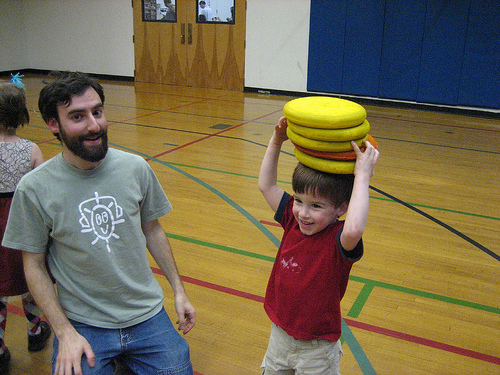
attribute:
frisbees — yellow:
[282, 93, 379, 174]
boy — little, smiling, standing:
[255, 115, 379, 374]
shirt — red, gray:
[262, 190, 365, 341]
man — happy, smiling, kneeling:
[2, 68, 197, 373]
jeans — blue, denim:
[53, 304, 195, 373]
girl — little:
[1, 70, 50, 362]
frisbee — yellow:
[283, 95, 366, 128]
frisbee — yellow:
[285, 118, 370, 140]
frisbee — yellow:
[284, 127, 369, 152]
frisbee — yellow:
[293, 147, 356, 174]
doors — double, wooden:
[132, 1, 246, 92]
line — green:
[20, 131, 499, 222]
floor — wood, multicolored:
[1, 72, 499, 374]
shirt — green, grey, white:
[2, 146, 172, 329]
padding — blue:
[305, 1, 499, 110]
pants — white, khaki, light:
[262, 321, 344, 374]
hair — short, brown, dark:
[292, 161, 355, 209]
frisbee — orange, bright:
[292, 134, 377, 159]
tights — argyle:
[1, 287, 43, 357]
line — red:
[146, 262, 498, 364]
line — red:
[135, 107, 285, 160]